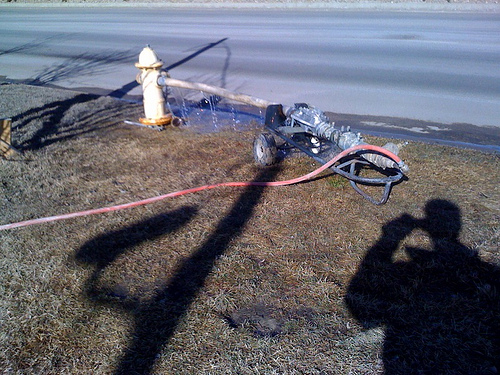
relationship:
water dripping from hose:
[166, 90, 265, 135] [169, 79, 261, 109]